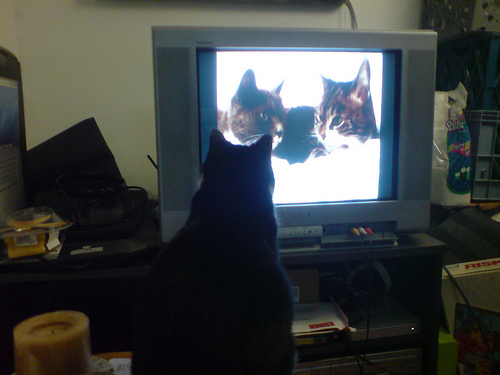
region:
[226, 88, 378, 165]
Cats on the television.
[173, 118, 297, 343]
A cat watching television.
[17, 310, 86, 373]
Candle on the table.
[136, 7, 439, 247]
Televison sitting on stand.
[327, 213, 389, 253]
Cords plugged in the tv.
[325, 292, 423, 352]
Dvd on the shelf of stand.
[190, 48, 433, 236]
The television is on.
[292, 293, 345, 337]
Papers on the shelf.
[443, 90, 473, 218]
Toilet paper on the chair.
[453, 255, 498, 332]
A box on the floor.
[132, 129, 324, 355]
a cat watching a tv screen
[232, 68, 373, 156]
two cat faces on a tv screen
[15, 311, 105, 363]
a yellow candle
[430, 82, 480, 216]
a plastic bag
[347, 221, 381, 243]
electrical connections for a tv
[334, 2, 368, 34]
a cord behind a tv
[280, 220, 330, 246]
knobs in front of a tv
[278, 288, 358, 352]
a magazine on a shelf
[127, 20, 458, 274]
a large television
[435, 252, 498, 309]
a box on the ground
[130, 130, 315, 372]
A cat sitting on the table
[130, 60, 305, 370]
A cat watching cats on TV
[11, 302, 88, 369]
A candle sitting on the table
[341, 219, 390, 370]
Cords plugged into the TV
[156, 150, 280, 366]
The cat is the color black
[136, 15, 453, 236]
The TV is the color gray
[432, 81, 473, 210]
A large package of toilet papers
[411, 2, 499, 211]
A stack of three crates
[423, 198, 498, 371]
Several items in the corner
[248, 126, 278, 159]
The ear of the cat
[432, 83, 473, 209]
Package of Quilted Northern toilet paper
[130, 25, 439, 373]
Cat watching the television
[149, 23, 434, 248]
Cat program playing on the television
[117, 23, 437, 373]
Black cat watching a cat program on the television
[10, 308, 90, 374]
Used dark yellow candle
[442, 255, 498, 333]
The board game Risk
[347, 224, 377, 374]
Video and audio hook up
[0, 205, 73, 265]
Plastic garbage container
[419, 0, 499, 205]
Stacked storage crates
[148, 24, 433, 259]
Old silver television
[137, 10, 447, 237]
a silver tv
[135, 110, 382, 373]
a cat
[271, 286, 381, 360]
a white and red netflix envelope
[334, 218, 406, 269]
yellow white and red cords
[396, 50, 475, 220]
a white shopping bag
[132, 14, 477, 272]
a tv with cats on it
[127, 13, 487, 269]
a silver tv with cats on it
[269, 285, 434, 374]
silver dvd player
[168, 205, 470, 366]
a black tv stand